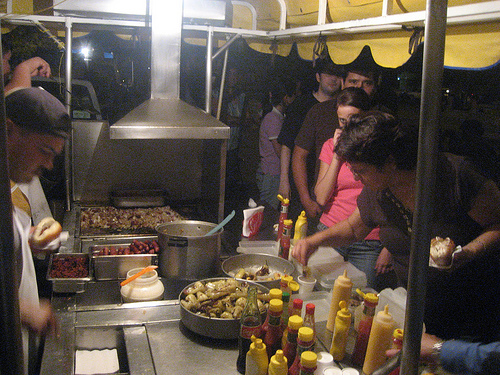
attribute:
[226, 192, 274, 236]
holder — red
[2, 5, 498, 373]
stand — hot dog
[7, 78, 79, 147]
cap — black, baseball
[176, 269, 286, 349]
pot — cooking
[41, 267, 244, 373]
surface — silver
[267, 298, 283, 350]
bottle — condiment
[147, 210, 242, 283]
pot of food — cooking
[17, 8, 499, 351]
hot dog stand — hot dog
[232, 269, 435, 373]
plastic bottles — pastic